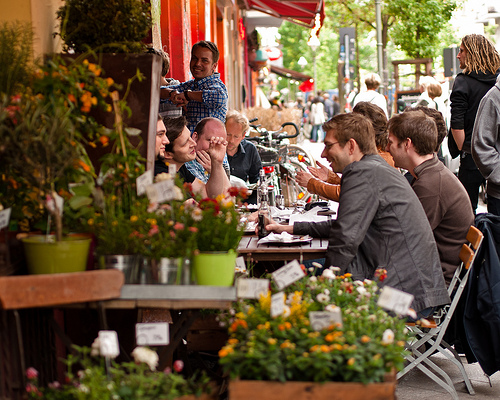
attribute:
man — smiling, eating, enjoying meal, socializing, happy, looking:
[162, 37, 229, 179]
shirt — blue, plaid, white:
[161, 76, 231, 178]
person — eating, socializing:
[154, 113, 231, 200]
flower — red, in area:
[228, 185, 240, 199]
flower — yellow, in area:
[215, 192, 227, 203]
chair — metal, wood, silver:
[394, 223, 485, 398]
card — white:
[273, 260, 308, 290]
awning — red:
[242, 0, 327, 37]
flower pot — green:
[22, 232, 91, 274]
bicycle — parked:
[242, 126, 317, 202]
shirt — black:
[442, 70, 498, 160]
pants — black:
[456, 154, 499, 219]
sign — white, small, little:
[138, 323, 170, 345]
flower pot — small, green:
[196, 251, 236, 286]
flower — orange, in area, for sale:
[79, 98, 91, 113]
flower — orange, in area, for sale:
[87, 64, 103, 74]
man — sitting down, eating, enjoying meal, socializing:
[251, 111, 451, 315]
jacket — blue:
[452, 212, 499, 388]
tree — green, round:
[322, 0, 460, 99]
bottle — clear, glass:
[258, 189, 271, 237]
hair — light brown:
[322, 111, 378, 154]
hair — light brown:
[386, 112, 435, 156]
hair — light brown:
[408, 105, 447, 152]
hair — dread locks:
[461, 35, 499, 76]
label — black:
[256, 211, 265, 235]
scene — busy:
[1, 0, 500, 399]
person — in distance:
[310, 94, 329, 142]